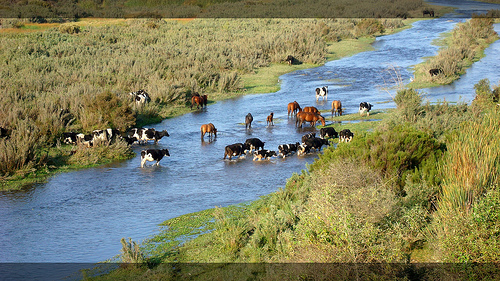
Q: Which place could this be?
A: It is a river.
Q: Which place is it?
A: It is a river.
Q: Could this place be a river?
A: Yes, it is a river.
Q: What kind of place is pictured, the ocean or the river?
A: It is the river.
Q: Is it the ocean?
A: No, it is the river.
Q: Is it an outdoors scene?
A: Yes, it is outdoors.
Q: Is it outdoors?
A: Yes, it is outdoors.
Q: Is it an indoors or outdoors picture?
A: It is outdoors.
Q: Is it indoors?
A: No, it is outdoors.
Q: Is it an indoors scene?
A: No, it is outdoors.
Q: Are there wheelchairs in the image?
A: No, there are no wheelchairs.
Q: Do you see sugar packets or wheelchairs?
A: No, there are no wheelchairs or sugar packets.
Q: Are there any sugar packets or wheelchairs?
A: No, there are no wheelchairs or sugar packets.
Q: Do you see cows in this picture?
A: Yes, there is a cow.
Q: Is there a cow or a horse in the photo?
A: Yes, there is a cow.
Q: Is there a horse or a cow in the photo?
A: Yes, there is a cow.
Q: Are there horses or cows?
A: Yes, there is a cow.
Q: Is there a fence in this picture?
A: No, there are no fences.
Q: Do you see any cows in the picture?
A: Yes, there is a cow.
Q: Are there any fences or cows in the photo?
A: Yes, there is a cow.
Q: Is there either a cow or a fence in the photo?
A: Yes, there is a cow.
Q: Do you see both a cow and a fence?
A: No, there is a cow but no fences.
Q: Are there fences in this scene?
A: No, there are no fences.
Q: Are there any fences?
A: No, there are no fences.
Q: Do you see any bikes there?
A: No, there are no bikes.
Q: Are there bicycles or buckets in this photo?
A: No, there are no bicycles or buckets.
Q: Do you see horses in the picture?
A: Yes, there is a horse.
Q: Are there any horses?
A: Yes, there is a horse.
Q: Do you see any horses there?
A: Yes, there is a horse.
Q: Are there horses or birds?
A: Yes, there is a horse.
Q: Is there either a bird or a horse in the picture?
A: Yes, there is a horse.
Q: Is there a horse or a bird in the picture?
A: Yes, there is a horse.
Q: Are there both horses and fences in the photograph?
A: No, there is a horse but no fences.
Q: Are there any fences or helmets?
A: No, there are no fences or helmets.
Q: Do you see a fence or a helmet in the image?
A: No, there are no fences or helmets.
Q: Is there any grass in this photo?
A: Yes, there is grass.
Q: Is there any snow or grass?
A: Yes, there is grass.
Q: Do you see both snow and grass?
A: No, there is grass but no snow.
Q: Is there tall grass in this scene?
A: Yes, there is tall grass.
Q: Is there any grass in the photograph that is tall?
A: Yes, there is grass that is tall.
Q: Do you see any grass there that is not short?
A: Yes, there is tall grass.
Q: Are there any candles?
A: No, there are no candles.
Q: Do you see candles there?
A: No, there are no candles.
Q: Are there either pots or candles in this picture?
A: No, there are no candles or pots.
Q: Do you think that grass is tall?
A: Yes, the grass is tall.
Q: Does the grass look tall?
A: Yes, the grass is tall.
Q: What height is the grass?
A: The grass is tall.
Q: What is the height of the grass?
A: The grass is tall.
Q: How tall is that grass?
A: The grass is tall.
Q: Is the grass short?
A: No, the grass is tall.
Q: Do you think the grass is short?
A: No, the grass is tall.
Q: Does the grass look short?
A: No, the grass is tall.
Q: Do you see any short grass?
A: No, there is grass but it is tall.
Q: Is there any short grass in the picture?
A: No, there is grass but it is tall.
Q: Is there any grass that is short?
A: No, there is grass but it is tall.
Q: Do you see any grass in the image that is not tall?
A: No, there is grass but it is tall.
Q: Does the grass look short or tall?
A: The grass is tall.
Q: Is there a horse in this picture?
A: Yes, there is a horse.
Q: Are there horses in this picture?
A: Yes, there is a horse.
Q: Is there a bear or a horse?
A: Yes, there is a horse.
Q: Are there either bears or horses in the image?
A: Yes, there is a horse.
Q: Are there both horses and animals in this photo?
A: Yes, there are both a horse and an animal.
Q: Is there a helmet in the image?
A: No, there are no helmets.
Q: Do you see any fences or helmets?
A: No, there are no helmets or fences.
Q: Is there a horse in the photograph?
A: Yes, there are horses.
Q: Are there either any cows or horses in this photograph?
A: Yes, there are horses.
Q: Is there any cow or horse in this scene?
A: Yes, there are horses.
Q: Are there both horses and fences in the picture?
A: No, there are horses but no fences.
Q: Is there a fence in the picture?
A: No, there are no fences.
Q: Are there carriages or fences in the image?
A: No, there are no fences or carriages.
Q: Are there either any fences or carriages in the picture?
A: No, there are no fences or carriages.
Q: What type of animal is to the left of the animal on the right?
A: The animals are horses.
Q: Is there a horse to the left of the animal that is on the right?
A: Yes, there are horses to the left of the animal.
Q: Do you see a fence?
A: No, there are no fences.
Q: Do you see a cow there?
A: Yes, there are cows.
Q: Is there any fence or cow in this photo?
A: Yes, there are cows.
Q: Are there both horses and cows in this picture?
A: Yes, there are both cows and a horse.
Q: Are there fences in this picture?
A: No, there are no fences.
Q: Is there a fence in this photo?
A: No, there are no fences.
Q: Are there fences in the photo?
A: No, there are no fences.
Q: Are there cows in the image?
A: Yes, there are cows.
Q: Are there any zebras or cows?
A: Yes, there are cows.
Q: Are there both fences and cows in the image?
A: No, there are cows but no fences.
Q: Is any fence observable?
A: No, there are no fences.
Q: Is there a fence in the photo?
A: No, there are no fences.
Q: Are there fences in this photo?
A: No, there are no fences.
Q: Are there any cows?
A: Yes, there are cows.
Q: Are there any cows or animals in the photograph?
A: Yes, there are cows.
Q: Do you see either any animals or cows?
A: Yes, there are cows.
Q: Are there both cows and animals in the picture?
A: Yes, there are both cows and an animal.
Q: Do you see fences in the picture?
A: No, there are no fences.